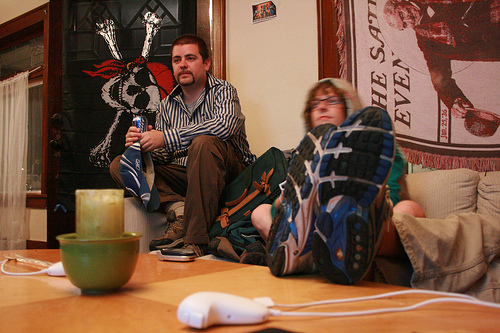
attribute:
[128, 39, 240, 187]
man — sitting, watching, looking, drinking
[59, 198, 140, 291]
bowl — green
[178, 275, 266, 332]
controller — white, small, visable, close, laying, wii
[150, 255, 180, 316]
table — brown, wooden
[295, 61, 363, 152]
woman — laying, nerdy, watching, white, relaxed, sitting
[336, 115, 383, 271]
sneakers — blue, dark, close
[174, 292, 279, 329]
controller — white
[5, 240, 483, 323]
surface — brown